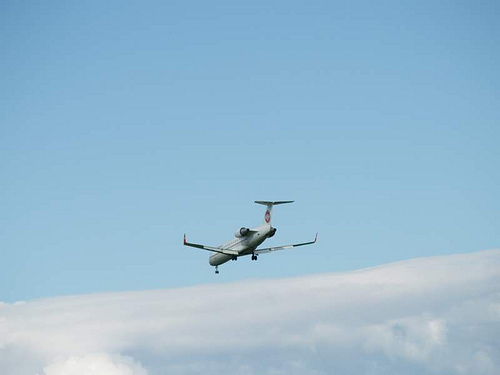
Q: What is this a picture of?
A: A plane.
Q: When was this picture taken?
A: During the day.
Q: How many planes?
A: One.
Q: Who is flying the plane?
A: The pilot.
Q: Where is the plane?
A: In the air.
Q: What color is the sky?
A: Blue.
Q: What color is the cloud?
A: White.